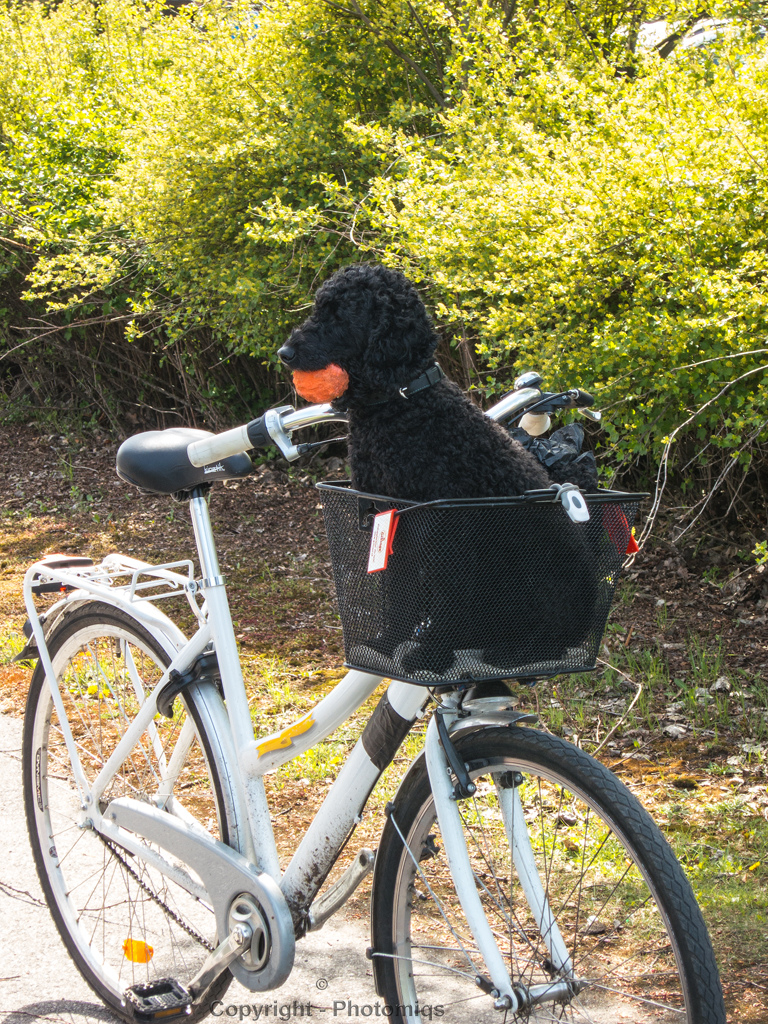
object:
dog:
[276, 266, 597, 674]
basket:
[315, 480, 651, 688]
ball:
[293, 362, 350, 403]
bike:
[13, 370, 727, 1024]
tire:
[366, 725, 728, 1023]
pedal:
[130, 977, 193, 1023]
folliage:
[343, 13, 768, 489]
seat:
[116, 427, 252, 496]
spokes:
[371, 770, 685, 1024]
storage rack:
[22, 551, 206, 627]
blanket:
[350, 640, 590, 683]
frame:
[189, 496, 284, 873]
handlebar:
[187, 370, 602, 468]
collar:
[362, 361, 449, 407]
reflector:
[122, 937, 153, 961]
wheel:
[22, 600, 233, 1024]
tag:
[367, 509, 400, 574]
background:
[0, 2, 767, 544]